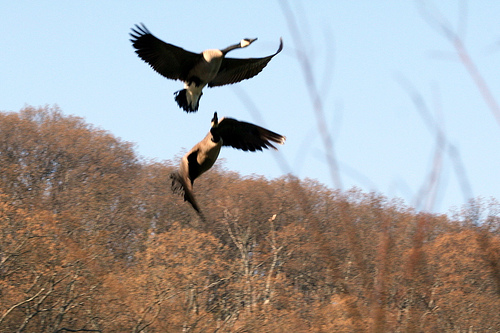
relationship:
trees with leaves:
[2, 107, 499, 332] [5, 111, 499, 331]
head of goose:
[236, 37, 259, 48] [128, 18, 285, 111]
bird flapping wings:
[168, 111, 287, 224] [179, 118, 284, 218]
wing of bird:
[126, 37, 184, 77] [127, 20, 283, 114]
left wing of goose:
[226, 40, 298, 87] [128, 18, 285, 111]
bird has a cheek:
[127, 20, 283, 114] [236, 39, 250, 49]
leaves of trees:
[5, 111, 499, 331] [2, 107, 499, 332]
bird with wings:
[127, 20, 283, 114] [125, 17, 285, 86]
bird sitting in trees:
[266, 212, 280, 224] [2, 107, 499, 332]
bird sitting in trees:
[127, 20, 283, 114] [2, 107, 499, 332]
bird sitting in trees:
[271, 214, 278, 222] [2, 107, 499, 332]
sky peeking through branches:
[1, 0, 499, 218] [36, 151, 67, 211]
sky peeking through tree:
[1, 0, 499, 218] [6, 105, 127, 234]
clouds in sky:
[59, 21, 101, 96] [5, 3, 464, 39]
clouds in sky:
[71, 28, 105, 88] [1, 0, 499, 218]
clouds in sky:
[411, 49, 465, 132] [1, 0, 499, 218]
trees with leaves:
[5, 95, 140, 300] [5, 111, 499, 331]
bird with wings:
[127, 20, 283, 114] [111, 22, 289, 89]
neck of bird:
[223, 41, 239, 61] [127, 20, 283, 114]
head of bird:
[236, 30, 261, 49] [127, 20, 283, 114]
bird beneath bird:
[163, 116, 277, 218] [120, 12, 288, 119]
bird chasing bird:
[127, 20, 283, 114] [168, 111, 287, 224]